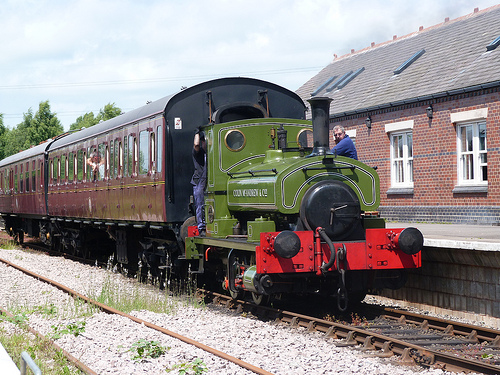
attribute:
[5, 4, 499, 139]
sky — blue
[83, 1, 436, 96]
clouds — white